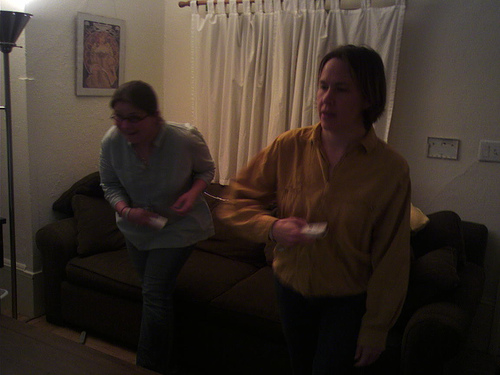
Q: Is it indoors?
A: Yes, it is indoors.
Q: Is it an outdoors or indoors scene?
A: It is indoors.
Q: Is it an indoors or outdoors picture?
A: It is indoors.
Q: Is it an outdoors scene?
A: No, it is indoors.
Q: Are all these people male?
A: No, they are both male and female.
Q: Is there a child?
A: No, there are no children.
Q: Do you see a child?
A: No, there are no children.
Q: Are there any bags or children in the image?
A: No, there are no children or bags.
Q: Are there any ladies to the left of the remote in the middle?
A: Yes, there is a lady to the left of the remote.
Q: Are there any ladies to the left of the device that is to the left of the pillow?
A: Yes, there is a lady to the left of the remote.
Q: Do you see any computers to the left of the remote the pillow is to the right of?
A: No, there is a lady to the left of the remote.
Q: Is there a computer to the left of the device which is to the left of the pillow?
A: No, there is a lady to the left of the remote.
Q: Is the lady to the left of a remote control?
A: Yes, the lady is to the left of a remote control.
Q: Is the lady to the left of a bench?
A: No, the lady is to the left of a remote control.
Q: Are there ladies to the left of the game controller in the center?
A: Yes, there is a lady to the left of the game controller.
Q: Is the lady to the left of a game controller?
A: Yes, the lady is to the left of a game controller.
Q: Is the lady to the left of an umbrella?
A: No, the lady is to the left of a game controller.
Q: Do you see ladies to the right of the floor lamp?
A: Yes, there is a lady to the right of the floor lamp.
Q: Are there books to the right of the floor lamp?
A: No, there is a lady to the right of the floor lamp.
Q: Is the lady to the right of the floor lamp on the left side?
A: Yes, the lady is to the right of the floor lamp.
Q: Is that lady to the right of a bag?
A: No, the lady is to the right of the floor lamp.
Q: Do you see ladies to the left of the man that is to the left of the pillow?
A: Yes, there is a lady to the left of the man.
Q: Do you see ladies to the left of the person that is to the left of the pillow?
A: Yes, there is a lady to the left of the man.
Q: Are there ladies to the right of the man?
A: No, the lady is to the left of the man.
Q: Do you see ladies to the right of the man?
A: No, the lady is to the left of the man.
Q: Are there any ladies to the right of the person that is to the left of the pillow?
A: No, the lady is to the left of the man.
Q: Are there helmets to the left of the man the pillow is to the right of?
A: No, there is a lady to the left of the man.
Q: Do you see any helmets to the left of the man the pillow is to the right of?
A: No, there is a lady to the left of the man.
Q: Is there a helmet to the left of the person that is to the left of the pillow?
A: No, there is a lady to the left of the man.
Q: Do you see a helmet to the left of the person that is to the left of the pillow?
A: No, there is a lady to the left of the man.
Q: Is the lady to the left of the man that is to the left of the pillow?
A: Yes, the lady is to the left of the man.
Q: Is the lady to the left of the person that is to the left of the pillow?
A: Yes, the lady is to the left of the man.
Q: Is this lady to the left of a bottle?
A: No, the lady is to the left of the man.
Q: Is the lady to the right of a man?
A: No, the lady is to the left of a man.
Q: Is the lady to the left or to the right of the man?
A: The lady is to the left of the man.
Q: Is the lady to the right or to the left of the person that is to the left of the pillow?
A: The lady is to the left of the man.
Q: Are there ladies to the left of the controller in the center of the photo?
A: Yes, there is a lady to the left of the controller.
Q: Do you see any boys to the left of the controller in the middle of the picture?
A: No, there is a lady to the left of the controller.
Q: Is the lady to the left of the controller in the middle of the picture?
A: Yes, the lady is to the left of the controller.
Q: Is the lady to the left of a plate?
A: No, the lady is to the left of the controller.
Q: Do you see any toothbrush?
A: No, there are no toothbrushes.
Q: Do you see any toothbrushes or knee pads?
A: No, there are no toothbrushes or knee pads.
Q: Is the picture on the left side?
A: Yes, the picture is on the left of the image.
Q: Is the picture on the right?
A: No, the picture is on the left of the image.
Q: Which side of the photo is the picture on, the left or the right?
A: The picture is on the left of the image.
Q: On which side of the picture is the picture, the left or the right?
A: The picture is on the left of the image.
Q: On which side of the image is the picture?
A: The picture is on the left of the image.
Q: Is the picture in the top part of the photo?
A: Yes, the picture is in the top of the image.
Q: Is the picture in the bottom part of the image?
A: No, the picture is in the top of the image.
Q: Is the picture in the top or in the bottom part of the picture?
A: The picture is in the top of the image.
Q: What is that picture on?
A: The picture is on the wall.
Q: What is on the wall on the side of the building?
A: The picture is on the wall.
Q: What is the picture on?
A: The picture is on the wall.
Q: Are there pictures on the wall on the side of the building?
A: Yes, there is a picture on the wall.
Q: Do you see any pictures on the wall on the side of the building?
A: Yes, there is a picture on the wall.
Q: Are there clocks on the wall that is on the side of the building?
A: No, there is a picture on the wall.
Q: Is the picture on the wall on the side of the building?
A: Yes, the picture is on the wall.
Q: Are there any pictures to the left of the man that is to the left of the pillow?
A: Yes, there is a picture to the left of the man.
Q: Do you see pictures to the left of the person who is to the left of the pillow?
A: Yes, there is a picture to the left of the man.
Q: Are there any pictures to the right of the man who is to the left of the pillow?
A: No, the picture is to the left of the man.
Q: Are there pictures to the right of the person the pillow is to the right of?
A: No, the picture is to the left of the man.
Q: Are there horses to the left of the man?
A: No, there is a picture to the left of the man.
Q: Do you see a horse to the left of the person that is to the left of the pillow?
A: No, there is a picture to the left of the man.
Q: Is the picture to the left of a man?
A: Yes, the picture is to the left of a man.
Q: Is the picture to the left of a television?
A: No, the picture is to the left of a man.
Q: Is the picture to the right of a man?
A: No, the picture is to the left of a man.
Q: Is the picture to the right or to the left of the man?
A: The picture is to the left of the man.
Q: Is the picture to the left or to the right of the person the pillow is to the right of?
A: The picture is to the left of the man.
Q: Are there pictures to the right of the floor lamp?
A: Yes, there is a picture to the right of the floor lamp.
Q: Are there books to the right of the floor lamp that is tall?
A: No, there is a picture to the right of the floor lamp.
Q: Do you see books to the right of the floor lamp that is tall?
A: No, there is a picture to the right of the floor lamp.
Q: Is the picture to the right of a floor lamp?
A: Yes, the picture is to the right of a floor lamp.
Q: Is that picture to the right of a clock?
A: No, the picture is to the right of a floor lamp.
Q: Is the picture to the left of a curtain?
A: Yes, the picture is to the left of a curtain.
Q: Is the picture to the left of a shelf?
A: No, the picture is to the left of a curtain.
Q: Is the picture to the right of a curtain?
A: No, the picture is to the left of a curtain.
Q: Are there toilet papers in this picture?
A: No, there are no toilet papers.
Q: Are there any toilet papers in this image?
A: No, there are no toilet papers.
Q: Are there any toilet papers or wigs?
A: No, there are no toilet papers or wigs.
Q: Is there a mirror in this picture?
A: No, there are no mirrors.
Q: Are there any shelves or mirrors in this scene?
A: No, there are no mirrors or shelves.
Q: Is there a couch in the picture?
A: Yes, there is a couch.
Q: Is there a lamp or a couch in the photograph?
A: Yes, there is a couch.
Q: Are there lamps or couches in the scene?
A: Yes, there is a couch.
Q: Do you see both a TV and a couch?
A: No, there is a couch but no televisions.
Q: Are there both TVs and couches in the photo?
A: No, there is a couch but no televisions.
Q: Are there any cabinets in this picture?
A: No, there are no cabinets.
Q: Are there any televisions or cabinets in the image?
A: No, there are no cabinets or televisions.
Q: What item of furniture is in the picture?
A: The piece of furniture is a couch.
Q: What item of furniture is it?
A: The piece of furniture is a couch.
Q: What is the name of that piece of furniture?
A: This is a couch.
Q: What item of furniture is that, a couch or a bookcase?
A: This is a couch.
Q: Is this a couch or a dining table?
A: This is a couch.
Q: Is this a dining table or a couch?
A: This is a couch.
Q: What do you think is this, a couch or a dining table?
A: This is a couch.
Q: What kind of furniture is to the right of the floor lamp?
A: The piece of furniture is a couch.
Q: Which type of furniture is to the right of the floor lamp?
A: The piece of furniture is a couch.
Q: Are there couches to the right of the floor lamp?
A: Yes, there is a couch to the right of the floor lamp.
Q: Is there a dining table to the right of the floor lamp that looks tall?
A: No, there is a couch to the right of the floor lamp.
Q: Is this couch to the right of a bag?
A: No, the couch is to the right of a floor lamp.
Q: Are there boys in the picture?
A: No, there are no boys.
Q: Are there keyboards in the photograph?
A: No, there are no keyboards.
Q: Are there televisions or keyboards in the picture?
A: No, there are no keyboards or televisions.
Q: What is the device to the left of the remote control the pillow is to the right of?
A: The device is a controller.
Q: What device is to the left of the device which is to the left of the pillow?
A: The device is a controller.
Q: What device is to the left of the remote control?
A: The device is a controller.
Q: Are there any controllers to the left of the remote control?
A: Yes, there is a controller to the left of the remote control.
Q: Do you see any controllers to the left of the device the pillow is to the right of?
A: Yes, there is a controller to the left of the remote control.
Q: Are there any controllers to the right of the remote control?
A: No, the controller is to the left of the remote control.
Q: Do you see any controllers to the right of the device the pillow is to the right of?
A: No, the controller is to the left of the remote control.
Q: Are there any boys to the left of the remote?
A: No, there is a controller to the left of the remote.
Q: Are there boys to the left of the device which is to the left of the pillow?
A: No, there is a controller to the left of the remote.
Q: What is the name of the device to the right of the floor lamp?
A: The device is a controller.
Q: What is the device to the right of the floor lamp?
A: The device is a controller.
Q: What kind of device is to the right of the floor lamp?
A: The device is a controller.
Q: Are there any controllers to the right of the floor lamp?
A: Yes, there is a controller to the right of the floor lamp.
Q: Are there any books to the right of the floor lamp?
A: No, there is a controller to the right of the floor lamp.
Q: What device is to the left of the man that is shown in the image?
A: The device is a controller.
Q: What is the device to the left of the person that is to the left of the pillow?
A: The device is a controller.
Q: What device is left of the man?
A: The device is a controller.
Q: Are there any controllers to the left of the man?
A: Yes, there is a controller to the left of the man.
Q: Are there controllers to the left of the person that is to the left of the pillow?
A: Yes, there is a controller to the left of the man.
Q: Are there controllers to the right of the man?
A: No, the controller is to the left of the man.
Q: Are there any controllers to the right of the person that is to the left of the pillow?
A: No, the controller is to the left of the man.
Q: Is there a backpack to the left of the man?
A: No, there is a controller to the left of the man.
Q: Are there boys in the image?
A: No, there are no boys.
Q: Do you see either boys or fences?
A: No, there are no boys or fences.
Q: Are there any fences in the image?
A: No, there are no fences.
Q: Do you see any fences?
A: No, there are no fences.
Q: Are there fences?
A: No, there are no fences.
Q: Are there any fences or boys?
A: No, there are no fences or boys.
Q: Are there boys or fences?
A: No, there are no fences or boys.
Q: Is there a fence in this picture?
A: No, there are no fences.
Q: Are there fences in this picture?
A: No, there are no fences.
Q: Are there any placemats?
A: No, there are no placemats.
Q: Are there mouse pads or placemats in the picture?
A: No, there are no placemats or mouse pads.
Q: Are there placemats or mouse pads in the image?
A: No, there are no placemats or mouse pads.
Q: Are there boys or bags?
A: No, there are no boys or bags.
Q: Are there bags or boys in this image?
A: No, there are no boys or bags.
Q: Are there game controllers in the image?
A: Yes, there is a game controller.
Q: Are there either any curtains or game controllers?
A: Yes, there is a game controller.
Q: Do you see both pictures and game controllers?
A: Yes, there are both a game controller and a picture.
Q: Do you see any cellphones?
A: No, there are no cellphones.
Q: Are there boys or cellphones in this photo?
A: No, there are no cellphones or boys.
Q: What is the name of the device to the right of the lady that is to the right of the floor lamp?
A: The device is a game controller.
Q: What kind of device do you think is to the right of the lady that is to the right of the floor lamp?
A: The device is a game controller.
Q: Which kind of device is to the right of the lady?
A: The device is a game controller.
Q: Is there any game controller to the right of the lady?
A: Yes, there is a game controller to the right of the lady.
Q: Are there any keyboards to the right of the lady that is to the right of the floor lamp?
A: No, there is a game controller to the right of the lady.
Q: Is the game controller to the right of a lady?
A: Yes, the game controller is to the right of a lady.